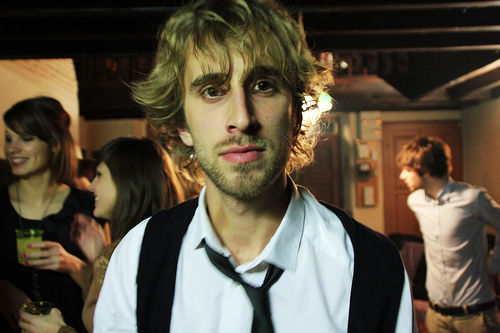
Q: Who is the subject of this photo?
A: The man.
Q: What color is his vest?
A: Black.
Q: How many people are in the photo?
A: 4.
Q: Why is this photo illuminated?
A: Light fixtures.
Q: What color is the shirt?
A: White.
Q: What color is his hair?
A: Blonde.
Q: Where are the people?
A: At a party.